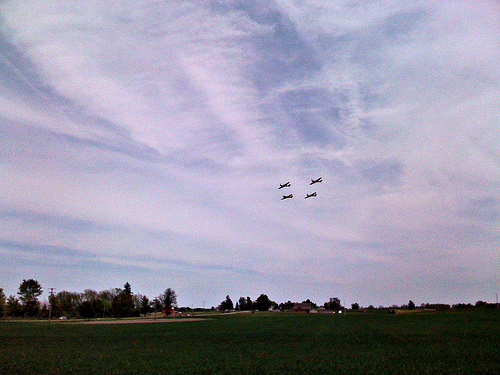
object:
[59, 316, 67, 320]
car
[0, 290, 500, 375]
background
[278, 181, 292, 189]
airplane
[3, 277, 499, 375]
field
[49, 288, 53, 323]
pole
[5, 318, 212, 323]
road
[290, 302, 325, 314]
buildings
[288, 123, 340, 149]
cloudy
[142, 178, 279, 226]
cloud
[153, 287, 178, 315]
tree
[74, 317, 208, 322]
dirt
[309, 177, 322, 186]
airplane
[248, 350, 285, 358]
grass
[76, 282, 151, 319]
trees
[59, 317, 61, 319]
headlight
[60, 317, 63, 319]
headlight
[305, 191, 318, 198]
planes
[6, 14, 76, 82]
sky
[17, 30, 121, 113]
cloud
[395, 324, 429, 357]
grass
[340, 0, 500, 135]
clouds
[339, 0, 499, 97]
sky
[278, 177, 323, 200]
four jets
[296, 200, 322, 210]
no subject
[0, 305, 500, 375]
ground